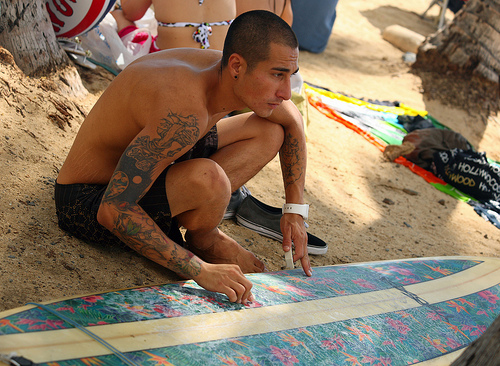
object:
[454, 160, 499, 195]
hollywood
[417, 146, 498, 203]
object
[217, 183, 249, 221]
sneakers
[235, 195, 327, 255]
sneakers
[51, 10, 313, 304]
man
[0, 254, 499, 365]
surfboard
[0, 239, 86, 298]
sand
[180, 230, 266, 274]
foot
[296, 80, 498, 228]
towel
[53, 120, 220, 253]
black shorts